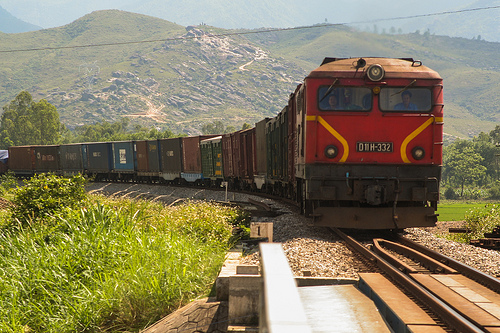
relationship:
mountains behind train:
[29, 11, 481, 31] [17, 50, 423, 205]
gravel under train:
[263, 211, 354, 275] [17, 50, 423, 205]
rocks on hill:
[135, 54, 248, 117] [46, 20, 286, 122]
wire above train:
[2, 3, 478, 63] [17, 50, 423, 205]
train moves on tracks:
[17, 50, 423, 205] [344, 220, 495, 313]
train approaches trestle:
[17, 50, 423, 205] [339, 239, 485, 323]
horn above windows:
[349, 56, 383, 77] [317, 74, 433, 112]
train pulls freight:
[17, 50, 423, 205] [0, 119, 217, 195]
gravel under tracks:
[263, 211, 354, 275] [344, 220, 495, 313]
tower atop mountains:
[311, 16, 339, 32] [29, 11, 481, 31]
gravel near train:
[263, 211, 354, 275] [17, 50, 423, 205]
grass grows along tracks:
[12, 218, 230, 330] [344, 220, 495, 313]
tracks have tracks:
[344, 220, 495, 313] [344, 220, 500, 333]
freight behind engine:
[0, 119, 217, 195] [306, 61, 445, 221]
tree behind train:
[370, 23, 378, 32] [17, 50, 423, 205]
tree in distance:
[370, 23, 378, 32] [0, 1, 497, 57]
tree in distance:
[383, 24, 390, 36] [0, 1, 497, 57]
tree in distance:
[398, 25, 404, 34] [0, 1, 497, 57]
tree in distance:
[413, 29, 422, 35] [0, 1, 497, 57]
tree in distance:
[423, 26, 431, 38] [0, 1, 497, 57]